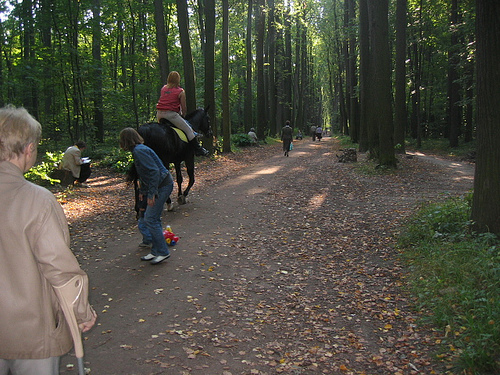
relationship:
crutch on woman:
[51, 270, 93, 374] [2, 102, 109, 374]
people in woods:
[114, 120, 179, 285] [9, 3, 490, 249]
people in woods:
[269, 116, 301, 153] [9, 3, 490, 249]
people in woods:
[2, 99, 97, 371] [9, 3, 490, 249]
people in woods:
[145, 59, 203, 158] [9, 3, 490, 249]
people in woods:
[236, 120, 264, 155] [9, 3, 490, 249]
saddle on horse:
[158, 116, 187, 141] [125, 106, 215, 226]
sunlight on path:
[42, 147, 332, 227] [59, 132, 476, 375]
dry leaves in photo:
[268, 177, 395, 367] [4, 6, 494, 368]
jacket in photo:
[134, 140, 169, 192] [4, 6, 494, 368]